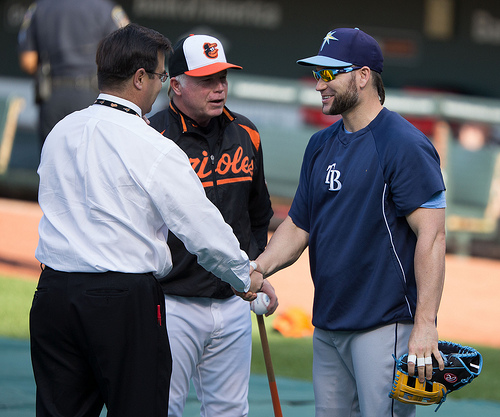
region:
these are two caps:
[183, 32, 382, 61]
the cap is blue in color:
[346, 32, 365, 54]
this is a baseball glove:
[397, 342, 482, 399]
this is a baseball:
[251, 290, 268, 312]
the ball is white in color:
[252, 294, 266, 309]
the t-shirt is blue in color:
[362, 132, 425, 189]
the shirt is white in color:
[71, 151, 147, 225]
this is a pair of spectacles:
[146, 65, 170, 81]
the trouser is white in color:
[183, 319, 196, 351]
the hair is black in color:
[106, 44, 136, 60]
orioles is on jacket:
[192, 146, 272, 190]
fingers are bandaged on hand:
[400, 355, 442, 372]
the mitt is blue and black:
[402, 344, 478, 394]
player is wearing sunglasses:
[310, 71, 353, 84]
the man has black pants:
[36, 274, 156, 416]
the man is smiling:
[319, 64, 372, 119]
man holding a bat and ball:
[242, 294, 287, 415]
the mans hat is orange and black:
[172, 40, 244, 79]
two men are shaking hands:
[218, 247, 284, 344]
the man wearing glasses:
[112, 71, 173, 90]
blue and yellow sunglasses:
[304, 67, 357, 82]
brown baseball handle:
[257, 316, 291, 415]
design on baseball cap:
[318, 24, 340, 52]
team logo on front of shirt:
[316, 156, 357, 202]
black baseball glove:
[406, 339, 483, 387]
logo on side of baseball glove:
[441, 363, 463, 391]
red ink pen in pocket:
[150, 299, 168, 334]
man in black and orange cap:
[161, 33, 251, 123]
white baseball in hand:
[243, 283, 278, 321]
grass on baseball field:
[275, 339, 312, 376]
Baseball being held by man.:
[245, 284, 277, 316]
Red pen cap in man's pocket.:
[154, 295, 166, 332]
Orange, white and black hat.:
[167, 31, 237, 77]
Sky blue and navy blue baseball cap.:
[299, 24, 386, 72]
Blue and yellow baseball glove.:
[385, 342, 483, 406]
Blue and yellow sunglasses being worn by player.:
[308, 69, 351, 81]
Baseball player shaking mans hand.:
[255, 22, 482, 414]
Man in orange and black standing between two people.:
[160, 27, 280, 415]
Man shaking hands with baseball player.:
[20, 25, 252, 414]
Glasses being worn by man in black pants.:
[152, 67, 174, 86]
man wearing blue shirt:
[236, 15, 466, 413]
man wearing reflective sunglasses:
[270, 17, 482, 414]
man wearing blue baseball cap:
[260, 23, 479, 413]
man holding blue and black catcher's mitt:
[253, 25, 498, 407]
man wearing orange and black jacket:
[119, 13, 297, 411]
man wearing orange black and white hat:
[125, 16, 292, 414]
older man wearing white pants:
[130, 23, 282, 413]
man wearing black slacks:
[18, 12, 259, 413]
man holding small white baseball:
[27, 20, 277, 411]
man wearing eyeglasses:
[18, 0, 272, 413]